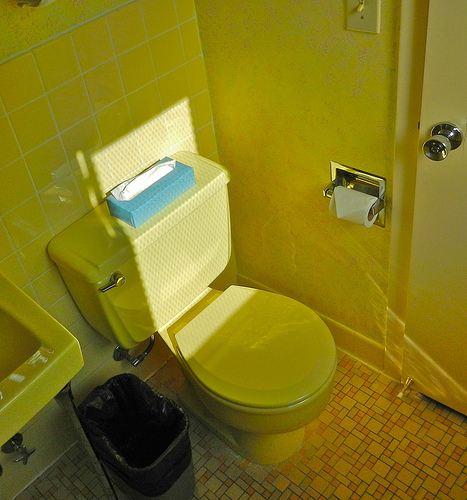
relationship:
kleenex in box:
[106, 154, 177, 203] [94, 154, 198, 232]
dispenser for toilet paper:
[312, 155, 390, 236] [324, 179, 382, 234]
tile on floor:
[9, 348, 463, 498] [0, 288, 464, 499]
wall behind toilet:
[1, 2, 241, 499] [41, 144, 343, 471]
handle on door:
[418, 112, 465, 172] [397, 2, 466, 423]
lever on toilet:
[94, 268, 127, 297] [41, 144, 343, 471]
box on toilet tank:
[105, 156, 198, 228] [43, 146, 236, 357]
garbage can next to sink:
[73, 371, 202, 499] [1, 270, 122, 500]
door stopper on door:
[392, 368, 416, 404] [397, 2, 466, 423]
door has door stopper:
[397, 2, 466, 423] [392, 368, 416, 404]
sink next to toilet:
[1, 270, 122, 500] [41, 144, 343, 471]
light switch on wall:
[337, 2, 386, 44] [196, 2, 401, 351]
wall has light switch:
[196, 2, 401, 351] [337, 2, 386, 44]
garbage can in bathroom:
[73, 371, 202, 499] [2, 2, 466, 500]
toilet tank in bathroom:
[43, 146, 236, 357] [2, 2, 466, 500]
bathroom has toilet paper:
[2, 2, 466, 500] [324, 179, 382, 234]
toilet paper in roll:
[324, 179, 382, 234] [362, 194, 380, 231]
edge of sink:
[0, 283, 93, 386] [1, 270, 122, 500]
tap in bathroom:
[3, 431, 41, 474] [2, 2, 466, 500]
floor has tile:
[0, 288, 464, 499] [9, 348, 463, 498]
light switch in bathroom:
[337, 2, 386, 44] [2, 2, 466, 500]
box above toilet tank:
[105, 156, 198, 228] [43, 146, 236, 357]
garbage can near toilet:
[73, 371, 202, 499] [41, 144, 343, 471]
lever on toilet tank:
[94, 268, 127, 297] [43, 146, 236, 357]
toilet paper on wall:
[324, 179, 382, 234] [196, 2, 401, 351]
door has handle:
[397, 2, 466, 423] [418, 112, 465, 172]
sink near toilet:
[1, 270, 122, 500] [41, 144, 343, 471]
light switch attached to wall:
[337, 2, 386, 44] [196, 2, 401, 351]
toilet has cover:
[41, 144, 343, 471] [172, 272, 339, 411]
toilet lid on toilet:
[170, 281, 340, 411] [41, 144, 343, 471]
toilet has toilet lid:
[41, 144, 343, 471] [170, 281, 340, 411]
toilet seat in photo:
[172, 278, 341, 412] [1, 2, 466, 498]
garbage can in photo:
[73, 371, 202, 499] [1, 2, 466, 498]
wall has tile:
[1, 2, 241, 499] [0, 4, 239, 499]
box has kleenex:
[94, 154, 198, 232] [106, 154, 177, 203]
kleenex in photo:
[106, 154, 177, 203] [1, 2, 466, 498]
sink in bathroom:
[1, 270, 122, 500] [2, 2, 466, 500]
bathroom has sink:
[2, 2, 466, 500] [1, 270, 122, 500]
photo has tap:
[1, 2, 466, 498] [3, 431, 41, 474]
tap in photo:
[3, 431, 41, 474] [1, 2, 466, 498]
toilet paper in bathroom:
[324, 179, 382, 234] [2, 2, 466, 500]